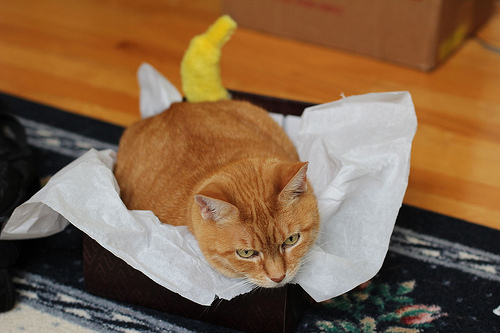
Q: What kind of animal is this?
A: A cat.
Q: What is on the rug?
A: Flowers.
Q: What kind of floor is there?
A: Wooden.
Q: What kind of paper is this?
A: White.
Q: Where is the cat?
A: On paper.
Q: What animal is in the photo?
A: A cat.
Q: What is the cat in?
A: A box.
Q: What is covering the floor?
A: A rug.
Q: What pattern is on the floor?
A: Floral.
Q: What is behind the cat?
A: A toy.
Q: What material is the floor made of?
A: Wood.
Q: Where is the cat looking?
A: Past the camera.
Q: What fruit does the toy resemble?
A: A banana.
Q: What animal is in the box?
A: A cat.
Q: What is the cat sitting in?
A: A box.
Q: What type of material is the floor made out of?
A: Wood.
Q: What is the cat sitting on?
A: Tissue paper.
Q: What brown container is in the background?
A: A cardboard box.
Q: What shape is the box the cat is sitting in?
A: A rectangle.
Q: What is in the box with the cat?
A: Tissue paper.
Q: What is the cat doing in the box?
A: Sitting.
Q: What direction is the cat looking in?
A: Down.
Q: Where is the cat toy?
A: Behind the cat.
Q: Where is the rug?
A: On the floor.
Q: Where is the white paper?
A: Under the cat.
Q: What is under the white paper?
A: A box.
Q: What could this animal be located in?
A: Box.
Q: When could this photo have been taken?
A: Daytime.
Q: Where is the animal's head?
A: Towards camera.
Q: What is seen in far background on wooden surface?
A: Box.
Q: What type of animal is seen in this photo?
A: Cat.